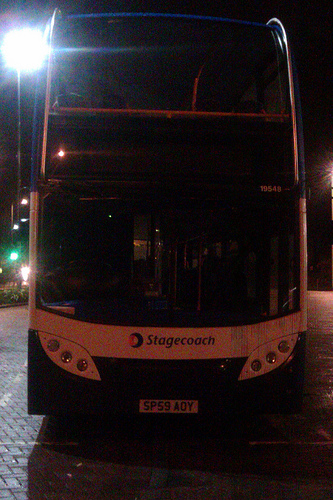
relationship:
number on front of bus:
[260, 183, 263, 191] [45, 8, 300, 431]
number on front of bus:
[260, 183, 263, 191] [36, 8, 302, 431]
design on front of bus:
[122, 324, 223, 356] [36, 8, 302, 431]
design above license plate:
[122, 324, 223, 356] [135, 386, 199, 415]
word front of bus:
[143, 330, 220, 350] [36, 8, 302, 431]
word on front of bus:
[180, 332, 220, 346] [36, 8, 302, 431]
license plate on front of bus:
[135, 386, 199, 415] [36, 8, 302, 431]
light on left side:
[3, 25, 52, 76] [1, 3, 201, 499]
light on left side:
[3, 238, 28, 265] [1, 3, 201, 499]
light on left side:
[15, 265, 38, 287] [1, 3, 201, 499]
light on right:
[275, 334, 294, 355] [165, 5, 327, 500]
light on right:
[264, 348, 280, 366] [165, 5, 327, 500]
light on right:
[245, 354, 262, 373] [165, 5, 327, 500]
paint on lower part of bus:
[29, 332, 307, 413] [36, 8, 302, 431]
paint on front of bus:
[29, 332, 307, 413] [36, 8, 302, 431]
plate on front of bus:
[135, 386, 199, 415] [36, 8, 302, 431]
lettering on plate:
[138, 392, 195, 413] [135, 386, 199, 415]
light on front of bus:
[46, 337, 93, 376] [36, 8, 302, 431]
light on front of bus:
[42, 333, 64, 354] [36, 8, 302, 431]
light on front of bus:
[59, 350, 75, 365] [36, 8, 302, 431]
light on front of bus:
[75, 354, 91, 374] [36, 8, 302, 431]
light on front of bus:
[245, 354, 262, 373] [36, 8, 302, 431]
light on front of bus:
[264, 348, 280, 366] [36, 8, 302, 431]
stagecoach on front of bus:
[143, 330, 220, 350] [36, 8, 302, 431]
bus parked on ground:
[36, 8, 302, 431] [3, 311, 330, 466]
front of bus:
[45, 8, 300, 431] [36, 8, 302, 431]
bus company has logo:
[122, 324, 223, 356] [121, 327, 222, 350]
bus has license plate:
[36, 8, 302, 431] [135, 386, 199, 415]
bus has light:
[36, 8, 302, 431] [42, 333, 64, 354]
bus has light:
[36, 8, 302, 431] [59, 350, 75, 365]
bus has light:
[36, 8, 302, 431] [75, 354, 91, 374]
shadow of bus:
[36, 418, 331, 481] [36, 8, 302, 431]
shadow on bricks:
[36, 418, 331, 481] [3, 311, 330, 466]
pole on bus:
[7, 43, 36, 254] [36, 8, 302, 431]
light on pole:
[3, 25, 52, 76] [7, 43, 36, 254]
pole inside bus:
[193, 209, 214, 314] [36, 8, 302, 431]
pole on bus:
[193, 209, 214, 314] [36, 8, 302, 431]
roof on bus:
[45, 8, 292, 39] [36, 8, 302, 431]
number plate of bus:
[135, 386, 199, 415] [36, 8, 302, 431]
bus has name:
[36, 8, 302, 431] [121, 327, 222, 350]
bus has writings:
[36, 8, 302, 431] [143, 330, 220, 350]